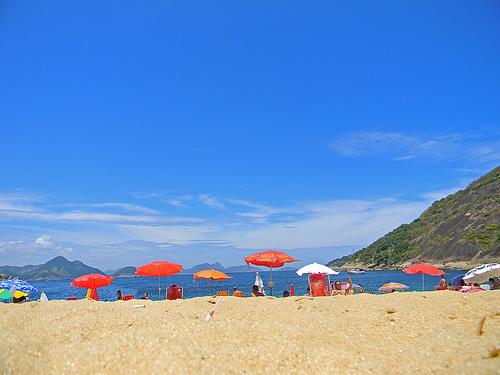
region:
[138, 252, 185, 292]
open red umbrella on beach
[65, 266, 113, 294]
open red umbrella on beach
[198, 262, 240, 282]
open red umbrella on beach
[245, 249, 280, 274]
open red umbrella on beach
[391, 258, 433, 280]
open red umbrella on beach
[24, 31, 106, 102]
white clouds in blue sky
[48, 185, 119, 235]
white clouds in blue sky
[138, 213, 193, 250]
white clouds in blue sky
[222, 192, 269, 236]
white clouds in blue sky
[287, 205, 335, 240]
white clouds in blue sky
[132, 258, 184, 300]
Red umbrella next to orange umbrella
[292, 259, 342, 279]
White umbrella next to red umbrella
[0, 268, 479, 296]
Blue ocean in front of orange umbrella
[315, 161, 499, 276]
Large mountain next to ocean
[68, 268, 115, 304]
Red umbrella stuck in sand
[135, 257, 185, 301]
Red umbrella stuck in sand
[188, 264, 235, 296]
Orange umbrella stuck in sand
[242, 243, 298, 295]
Red umbrella stuck in sand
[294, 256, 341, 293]
White umbrella stuck in sand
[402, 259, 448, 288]
Red umbrella stuck in sand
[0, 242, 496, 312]
people and open umbrellas at the beach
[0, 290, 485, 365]
curved mound of sand with cigarette butts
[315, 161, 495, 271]
rocky mountain sloping into ocean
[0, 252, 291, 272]
mountains on other side of ocean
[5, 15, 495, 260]
blue sky edged with white clouds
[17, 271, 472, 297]
tranquil deep-blue water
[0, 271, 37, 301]
low blue and white umbrella at end of row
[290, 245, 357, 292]
person in chair facing away from water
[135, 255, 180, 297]
person in chair under orange umbrella facing water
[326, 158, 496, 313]
plants growing around flat outcrops of rock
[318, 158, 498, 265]
Large mountain next to blue ocean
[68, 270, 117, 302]
Red umbrella stuck into sand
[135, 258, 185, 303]
Red umbrella stuck into sand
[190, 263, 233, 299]
Orange umbrella stuck into sand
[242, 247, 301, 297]
Red umbrella stuck into sand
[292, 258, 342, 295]
White umbrella stuck into sand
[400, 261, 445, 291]
Red umbrella stuck into sand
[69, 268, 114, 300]
Red umbrella next to red umbrella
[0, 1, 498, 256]
the clouds in the blue sky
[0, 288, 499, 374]
the sand at the beach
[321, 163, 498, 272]
the greenery on the mountain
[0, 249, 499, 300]
the opened umbrellas at the beach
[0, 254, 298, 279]
the mountains in the distance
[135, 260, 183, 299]
the opened umbrella near the water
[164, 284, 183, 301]
the beach chair under the umbrella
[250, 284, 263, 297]
the person sitting under the umbrella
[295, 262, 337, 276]
the opened white umbrella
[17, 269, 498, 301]
the body of water